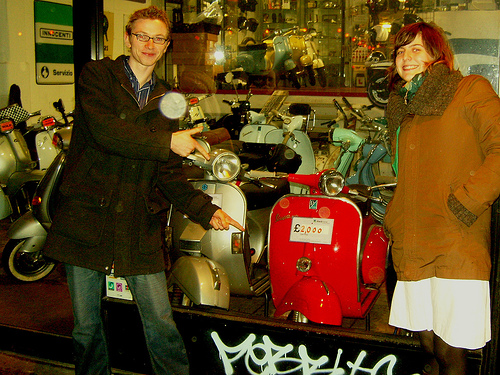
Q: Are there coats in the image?
A: Yes, there is a coat.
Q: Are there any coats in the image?
A: Yes, there is a coat.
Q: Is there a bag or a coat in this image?
A: Yes, there is a coat.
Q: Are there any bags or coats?
A: Yes, there is a coat.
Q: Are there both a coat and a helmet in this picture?
A: No, there is a coat but no helmets.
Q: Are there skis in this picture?
A: No, there are no skis.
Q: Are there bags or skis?
A: No, there are no skis or bags.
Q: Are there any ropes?
A: No, there are no ropes.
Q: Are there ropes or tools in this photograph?
A: No, there are no ropes or tools.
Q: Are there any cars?
A: No, there are no cars.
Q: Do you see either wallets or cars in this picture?
A: No, there are no cars or wallets.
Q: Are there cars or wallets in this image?
A: No, there are no cars or wallets.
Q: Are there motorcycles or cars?
A: Yes, there is a motorcycle.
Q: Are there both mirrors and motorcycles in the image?
A: Yes, there are both a motorcycle and a mirror.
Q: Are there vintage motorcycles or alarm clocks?
A: Yes, there is a vintage motorcycle.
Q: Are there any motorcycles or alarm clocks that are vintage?
A: Yes, the motorcycle is vintage.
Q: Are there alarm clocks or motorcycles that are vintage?
A: Yes, the motorcycle is vintage.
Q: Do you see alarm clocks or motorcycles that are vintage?
A: Yes, the motorcycle is vintage.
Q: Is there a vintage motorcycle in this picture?
A: Yes, there is a vintage motorcycle.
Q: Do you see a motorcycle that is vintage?
A: Yes, there is a motorcycle that is vintage.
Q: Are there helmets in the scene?
A: No, there are no helmets.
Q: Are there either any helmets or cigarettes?
A: No, there are no helmets or cigarettes.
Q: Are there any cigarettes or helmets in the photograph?
A: No, there are no helmets or cigarettes.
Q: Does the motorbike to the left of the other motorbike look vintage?
A: Yes, the motorbike is vintage.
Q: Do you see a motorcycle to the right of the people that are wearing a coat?
A: No, the motorcycle is to the left of the people.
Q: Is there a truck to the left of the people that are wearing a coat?
A: No, there is a motorcycle to the left of the people.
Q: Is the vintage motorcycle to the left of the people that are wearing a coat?
A: Yes, the motorbike is to the left of the people.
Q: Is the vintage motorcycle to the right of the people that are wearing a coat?
A: No, the motorbike is to the left of the people.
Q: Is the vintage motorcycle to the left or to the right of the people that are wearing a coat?
A: The motorbike is to the left of the people.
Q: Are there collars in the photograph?
A: Yes, there is a collar.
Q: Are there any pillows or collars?
A: Yes, there is a collar.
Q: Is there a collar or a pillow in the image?
A: Yes, there is a collar.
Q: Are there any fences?
A: No, there are no fences.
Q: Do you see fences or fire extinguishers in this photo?
A: No, there are no fences or fire extinguishers.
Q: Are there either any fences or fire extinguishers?
A: No, there are no fences or fire extinguishers.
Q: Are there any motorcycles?
A: Yes, there is a motorcycle.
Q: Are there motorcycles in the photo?
A: Yes, there is a motorcycle.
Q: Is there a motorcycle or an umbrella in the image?
A: Yes, there is a motorcycle.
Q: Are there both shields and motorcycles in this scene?
A: No, there is a motorcycle but no shields.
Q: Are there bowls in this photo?
A: No, there are no bowls.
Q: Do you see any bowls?
A: No, there are no bowls.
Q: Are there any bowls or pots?
A: No, there are no bowls or pots.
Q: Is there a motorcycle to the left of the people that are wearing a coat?
A: Yes, there is a motorcycle to the left of the people.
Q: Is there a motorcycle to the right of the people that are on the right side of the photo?
A: No, the motorcycle is to the left of the people.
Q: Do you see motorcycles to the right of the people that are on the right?
A: No, the motorcycle is to the left of the people.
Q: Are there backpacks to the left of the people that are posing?
A: No, there is a motorcycle to the left of the people.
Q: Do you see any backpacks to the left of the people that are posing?
A: No, there is a motorcycle to the left of the people.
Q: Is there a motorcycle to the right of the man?
A: Yes, there is a motorcycle to the right of the man.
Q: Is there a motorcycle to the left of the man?
A: No, the motorcycle is to the right of the man.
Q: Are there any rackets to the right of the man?
A: No, there is a motorcycle to the right of the man.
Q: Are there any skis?
A: No, there are no skis.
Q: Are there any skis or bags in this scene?
A: No, there are no skis or bags.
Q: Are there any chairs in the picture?
A: No, there are no chairs.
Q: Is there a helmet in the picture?
A: No, there are no helmets.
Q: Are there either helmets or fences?
A: No, there are no helmets or fences.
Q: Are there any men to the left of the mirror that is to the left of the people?
A: Yes, there is a man to the left of the mirror.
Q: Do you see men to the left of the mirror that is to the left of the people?
A: Yes, there is a man to the left of the mirror.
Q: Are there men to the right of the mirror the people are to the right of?
A: No, the man is to the left of the mirror.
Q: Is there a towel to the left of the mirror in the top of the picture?
A: No, there is a man to the left of the mirror.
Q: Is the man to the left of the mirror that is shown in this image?
A: Yes, the man is to the left of the mirror.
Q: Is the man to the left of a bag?
A: No, the man is to the left of the mirror.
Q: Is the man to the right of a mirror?
A: No, the man is to the left of a mirror.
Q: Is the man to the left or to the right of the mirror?
A: The man is to the left of the mirror.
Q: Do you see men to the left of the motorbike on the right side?
A: Yes, there is a man to the left of the motorcycle.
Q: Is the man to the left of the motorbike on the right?
A: Yes, the man is to the left of the motorbike.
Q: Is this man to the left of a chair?
A: No, the man is to the left of the motorbike.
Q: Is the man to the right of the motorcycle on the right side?
A: No, the man is to the left of the motorbike.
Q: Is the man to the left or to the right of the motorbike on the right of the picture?
A: The man is to the left of the motorbike.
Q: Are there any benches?
A: No, there are no benches.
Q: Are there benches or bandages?
A: No, there are no benches or bandages.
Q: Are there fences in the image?
A: No, there are no fences.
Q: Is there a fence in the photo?
A: No, there are no fences.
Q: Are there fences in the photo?
A: No, there are no fences.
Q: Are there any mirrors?
A: Yes, there is a mirror.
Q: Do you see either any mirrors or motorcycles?
A: Yes, there is a mirror.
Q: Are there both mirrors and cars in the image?
A: No, there is a mirror but no cars.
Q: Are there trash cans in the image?
A: No, there are no trash cans.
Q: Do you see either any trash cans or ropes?
A: No, there are no trash cans or ropes.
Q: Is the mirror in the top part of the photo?
A: Yes, the mirror is in the top of the image.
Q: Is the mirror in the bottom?
A: No, the mirror is in the top of the image.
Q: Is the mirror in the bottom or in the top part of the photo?
A: The mirror is in the top of the image.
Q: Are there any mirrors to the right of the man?
A: Yes, there is a mirror to the right of the man.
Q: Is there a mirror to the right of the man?
A: Yes, there is a mirror to the right of the man.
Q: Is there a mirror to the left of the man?
A: No, the mirror is to the right of the man.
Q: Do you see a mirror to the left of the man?
A: No, the mirror is to the right of the man.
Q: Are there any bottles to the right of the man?
A: No, there is a mirror to the right of the man.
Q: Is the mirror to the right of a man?
A: Yes, the mirror is to the right of a man.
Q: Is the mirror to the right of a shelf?
A: No, the mirror is to the right of a man.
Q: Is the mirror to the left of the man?
A: No, the mirror is to the right of the man.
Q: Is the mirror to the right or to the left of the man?
A: The mirror is to the right of the man.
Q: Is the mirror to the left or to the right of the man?
A: The mirror is to the right of the man.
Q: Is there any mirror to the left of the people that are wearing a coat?
A: Yes, there is a mirror to the left of the people.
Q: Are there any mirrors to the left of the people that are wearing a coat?
A: Yes, there is a mirror to the left of the people.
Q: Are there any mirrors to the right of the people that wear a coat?
A: No, the mirror is to the left of the people.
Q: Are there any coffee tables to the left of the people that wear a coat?
A: No, there is a mirror to the left of the people.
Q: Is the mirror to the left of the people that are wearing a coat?
A: Yes, the mirror is to the left of the people.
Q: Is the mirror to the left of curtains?
A: No, the mirror is to the left of the people.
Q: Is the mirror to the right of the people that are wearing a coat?
A: No, the mirror is to the left of the people.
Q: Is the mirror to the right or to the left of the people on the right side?
A: The mirror is to the left of the people.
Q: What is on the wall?
A: The mirror is on the wall.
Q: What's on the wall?
A: The mirror is on the wall.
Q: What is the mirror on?
A: The mirror is on the wall.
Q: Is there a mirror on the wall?
A: Yes, there is a mirror on the wall.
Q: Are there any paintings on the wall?
A: No, there is a mirror on the wall.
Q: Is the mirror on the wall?
A: Yes, the mirror is on the wall.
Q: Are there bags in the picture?
A: No, there are no bags.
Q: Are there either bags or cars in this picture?
A: No, there are no bags or cars.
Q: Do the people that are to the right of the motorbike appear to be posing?
A: Yes, the people are posing.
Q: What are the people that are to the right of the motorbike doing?
A: The people are posing.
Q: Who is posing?
A: The people are posing.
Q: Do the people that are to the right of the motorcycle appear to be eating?
A: No, the people are posing.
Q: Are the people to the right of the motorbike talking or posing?
A: The people are posing.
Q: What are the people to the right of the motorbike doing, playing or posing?
A: The people are posing.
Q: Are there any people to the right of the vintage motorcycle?
A: Yes, there are people to the right of the motorbike.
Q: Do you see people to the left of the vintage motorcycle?
A: No, the people are to the right of the motorbike.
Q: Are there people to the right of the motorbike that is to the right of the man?
A: Yes, there are people to the right of the motorcycle.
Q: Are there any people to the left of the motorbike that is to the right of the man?
A: No, the people are to the right of the motorcycle.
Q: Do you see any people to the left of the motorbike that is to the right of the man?
A: No, the people are to the right of the motorcycle.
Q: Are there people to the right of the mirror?
A: Yes, there are people to the right of the mirror.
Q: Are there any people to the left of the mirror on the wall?
A: No, the people are to the right of the mirror.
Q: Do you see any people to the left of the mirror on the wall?
A: No, the people are to the right of the mirror.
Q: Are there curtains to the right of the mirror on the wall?
A: No, there are people to the right of the mirror.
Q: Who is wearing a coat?
A: The people are wearing a coat.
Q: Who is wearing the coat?
A: The people are wearing a coat.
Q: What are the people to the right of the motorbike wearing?
A: The people are wearing a coat.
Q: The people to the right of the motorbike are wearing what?
A: The people are wearing a coat.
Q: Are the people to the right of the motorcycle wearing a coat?
A: Yes, the people are wearing a coat.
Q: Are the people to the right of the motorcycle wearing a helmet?
A: No, the people are wearing a coat.